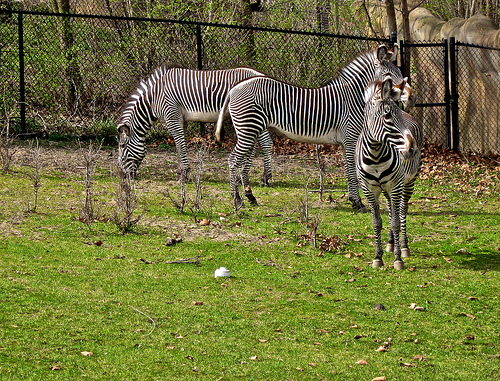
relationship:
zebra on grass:
[355, 81, 424, 269] [4, 172, 496, 379]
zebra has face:
[355, 81, 424, 269] [367, 79, 417, 156]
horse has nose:
[355, 81, 424, 269] [404, 123, 417, 164]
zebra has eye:
[355, 81, 424, 269] [380, 101, 396, 119]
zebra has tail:
[355, 81, 424, 269] [213, 96, 231, 146]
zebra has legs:
[355, 81, 424, 269] [166, 118, 415, 272]